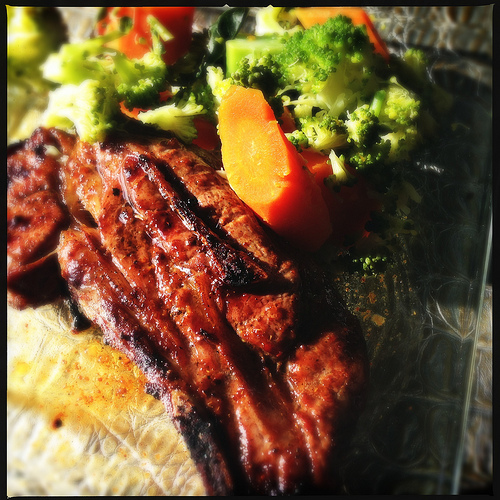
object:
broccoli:
[34, 14, 173, 104]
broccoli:
[140, 84, 217, 139]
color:
[74, 172, 113, 218]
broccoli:
[265, 11, 424, 180]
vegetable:
[220, 10, 435, 196]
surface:
[0, 305, 202, 496]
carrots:
[290, 8, 397, 59]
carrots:
[83, 14, 207, 56]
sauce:
[171, 278, 210, 333]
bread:
[4, 371, 139, 498]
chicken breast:
[0, 121, 371, 500]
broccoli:
[133, 90, 206, 145]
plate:
[266, 0, 496, 500]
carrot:
[214, 85, 333, 247]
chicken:
[116, 178, 197, 233]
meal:
[0, 0, 410, 491]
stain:
[51, 412, 63, 431]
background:
[358, 8, 495, 496]